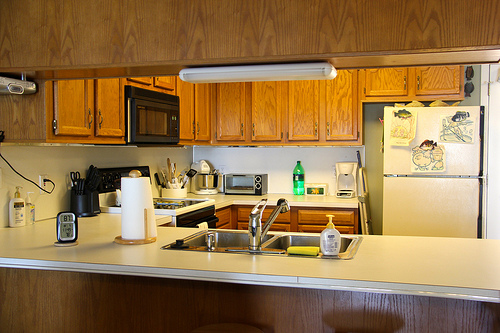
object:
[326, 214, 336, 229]
yellow top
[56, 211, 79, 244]
clock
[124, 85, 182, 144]
microwave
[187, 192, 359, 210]
countertop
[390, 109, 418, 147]
drawing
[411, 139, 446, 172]
drawing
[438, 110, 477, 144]
drawing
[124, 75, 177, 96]
cabinet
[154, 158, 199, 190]
utensils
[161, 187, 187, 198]
container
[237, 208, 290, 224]
drawer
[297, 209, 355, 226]
drawer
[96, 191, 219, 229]
stove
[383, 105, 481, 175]
refrigerator door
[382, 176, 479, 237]
refrigerator door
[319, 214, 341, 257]
soap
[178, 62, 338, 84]
light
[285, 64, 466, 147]
cabinets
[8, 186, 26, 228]
bottle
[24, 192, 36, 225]
bottle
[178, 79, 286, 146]
cabinets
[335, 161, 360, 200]
coffee maker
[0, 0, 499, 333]
kitchen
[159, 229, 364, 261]
sink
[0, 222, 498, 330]
counter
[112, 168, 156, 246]
holder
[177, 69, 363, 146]
cabinet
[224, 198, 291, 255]
faucet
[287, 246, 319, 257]
sponge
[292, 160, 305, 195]
bottle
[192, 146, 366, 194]
wall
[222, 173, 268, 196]
appliance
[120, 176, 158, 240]
paper towel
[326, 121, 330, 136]
handle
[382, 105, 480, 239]
refrigerator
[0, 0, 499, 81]
cabinet